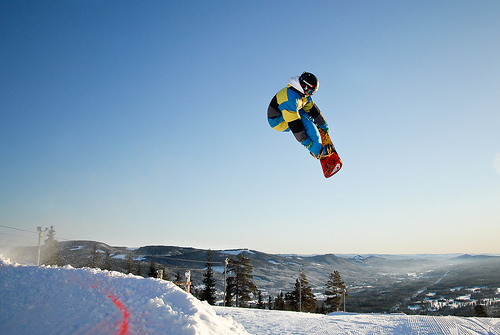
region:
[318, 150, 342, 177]
orange and black snowboard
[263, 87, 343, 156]
blue yellow and black jacket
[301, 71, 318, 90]
black plastic helmet on head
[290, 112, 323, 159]
blue pants ski pants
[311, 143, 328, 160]
blue and yellow glove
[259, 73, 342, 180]
person riding snow board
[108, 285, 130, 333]
orange paint in snow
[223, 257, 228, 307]
grey metal lamp post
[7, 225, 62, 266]
dust of snow in air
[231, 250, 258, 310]
tree with green leaves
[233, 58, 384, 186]
snow boarder in middle of a jump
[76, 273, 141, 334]
orange line in snow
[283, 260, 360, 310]
pine trees along ski path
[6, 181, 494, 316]
looking over cliff of mountain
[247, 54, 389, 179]
man wearing orange and blue jacket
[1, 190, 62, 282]
power lines above ski slope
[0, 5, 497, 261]
no clouds in sky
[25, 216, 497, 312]
rolling hills and mountains in distance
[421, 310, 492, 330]
tire tracks in snow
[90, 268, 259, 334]
sun casting shadows on snow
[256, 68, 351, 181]
the snowboarder is in mid jump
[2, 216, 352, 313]
this is a ski lift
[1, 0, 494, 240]
the sky is cloudless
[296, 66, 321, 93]
the snowboarder's helmet is black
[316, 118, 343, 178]
the snowboard is red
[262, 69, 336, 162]
the snowboarder is wearing black grey yellow and blue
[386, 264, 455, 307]
a roadway is seen in the distance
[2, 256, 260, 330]
this snowpile is the jump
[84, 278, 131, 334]
the read marking is to guide the snowboarder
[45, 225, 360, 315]
trees line the edge of the course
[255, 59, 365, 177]
snowboarder in mid air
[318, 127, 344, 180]
snow board used by person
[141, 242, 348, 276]
mountains in the background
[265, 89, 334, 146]
cold weather gear worn by person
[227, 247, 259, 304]
tree in group of several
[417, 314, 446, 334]
track marks in the snow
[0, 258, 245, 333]
pile of snow with orange mark in it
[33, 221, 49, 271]
utility pole with power lines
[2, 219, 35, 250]
power lines hanging from utility pole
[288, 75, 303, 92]
white hood on cold weather attire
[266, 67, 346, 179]
Athletic snowboarder in flight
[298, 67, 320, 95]
Athletic snowboarder black helmet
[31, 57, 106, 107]
Clear blue winter sky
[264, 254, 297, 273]
Part of distant hillside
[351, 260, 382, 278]
Part of distant hillside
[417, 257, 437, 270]
Part of distant hillside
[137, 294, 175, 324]
Snowy winter hillside drift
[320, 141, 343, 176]
Red snowboard of athlete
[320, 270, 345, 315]
Evergreen Tree on hillside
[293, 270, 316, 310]
Evergreen tree on hillside